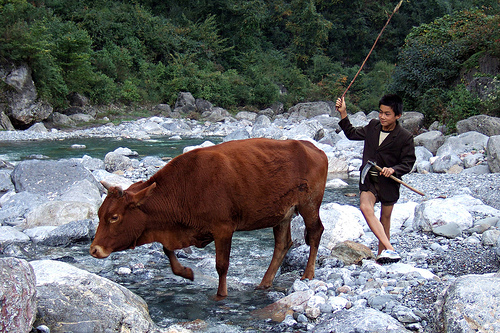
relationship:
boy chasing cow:
[335, 94, 416, 264] [82, 119, 333, 307]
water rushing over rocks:
[4, 136, 233, 226] [3, 150, 174, 255]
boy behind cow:
[335, 94, 416, 264] [82, 119, 333, 307]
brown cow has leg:
[89, 138, 329, 301] [160, 240, 189, 291]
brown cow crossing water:
[89, 138, 329, 301] [1, 137, 389, 332]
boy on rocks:
[335, 94, 416, 264] [5, 90, 497, 330]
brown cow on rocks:
[89, 138, 329, 301] [5, 90, 497, 330]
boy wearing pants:
[335, 94, 416, 264] [357, 168, 404, 210]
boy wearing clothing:
[335, 94, 416, 264] [336, 114, 416, 205]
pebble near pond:
[184, 317, 210, 331] [1, 131, 226, 161]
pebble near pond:
[337, 286, 349, 293] [1, 131, 226, 161]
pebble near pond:
[269, 307, 285, 324] [1, 131, 226, 161]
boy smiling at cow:
[329, 86, 416, 262] [70, 137, 332, 309]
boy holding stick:
[335, 94, 416, 264] [357, 5, 420, 105]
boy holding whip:
[335, 94, 416, 264] [324, 0, 406, 106]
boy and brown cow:
[329, 86, 416, 262] [89, 138, 329, 301]